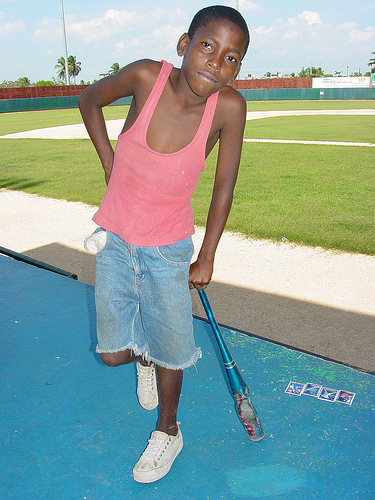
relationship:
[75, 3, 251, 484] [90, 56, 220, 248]
boy wears top